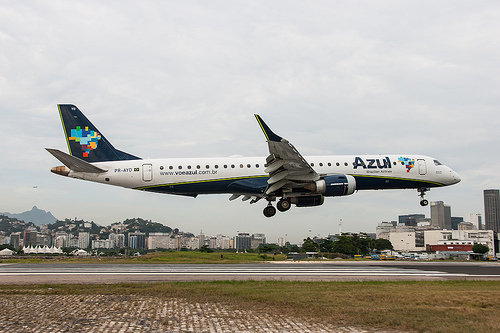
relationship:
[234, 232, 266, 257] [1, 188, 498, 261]
building in city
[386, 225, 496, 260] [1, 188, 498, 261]
building in city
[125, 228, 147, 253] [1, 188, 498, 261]
building in city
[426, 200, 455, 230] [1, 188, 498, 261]
building in city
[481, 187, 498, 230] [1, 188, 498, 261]
building in city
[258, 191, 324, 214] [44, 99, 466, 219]
gear on airplane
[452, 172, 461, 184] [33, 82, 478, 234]
nose on plane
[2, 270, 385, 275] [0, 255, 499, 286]
lines on tarmac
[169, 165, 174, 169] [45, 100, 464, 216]
window on airplane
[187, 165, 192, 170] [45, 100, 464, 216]
window on airplane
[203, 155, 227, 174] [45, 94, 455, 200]
window on airplane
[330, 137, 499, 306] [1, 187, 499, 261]
building in city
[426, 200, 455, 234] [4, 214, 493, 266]
building in city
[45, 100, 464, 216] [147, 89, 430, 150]
airplane flying air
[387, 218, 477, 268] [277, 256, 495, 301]
building near tarmac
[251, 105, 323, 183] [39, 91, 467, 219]
wing of airplane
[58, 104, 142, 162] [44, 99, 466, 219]
tail on airplane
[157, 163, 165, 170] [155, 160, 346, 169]
window of row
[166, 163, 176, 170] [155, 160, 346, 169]
window of row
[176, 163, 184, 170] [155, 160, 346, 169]
window of row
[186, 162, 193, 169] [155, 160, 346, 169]
window of row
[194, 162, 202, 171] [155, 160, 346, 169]
window of row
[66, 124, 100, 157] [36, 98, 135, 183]
decal on tail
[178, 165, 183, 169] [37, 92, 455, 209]
window on airplane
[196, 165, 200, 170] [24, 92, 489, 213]
window on airplane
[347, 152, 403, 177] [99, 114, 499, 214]
company on plane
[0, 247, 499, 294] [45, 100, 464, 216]
tarmac for airplane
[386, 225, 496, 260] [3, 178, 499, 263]
building in background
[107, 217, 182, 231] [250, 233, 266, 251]
hill behind building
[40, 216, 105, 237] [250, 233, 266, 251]
hill behind building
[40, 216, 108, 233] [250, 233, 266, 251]
hill behind building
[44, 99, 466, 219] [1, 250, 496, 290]
airplane approaching landing